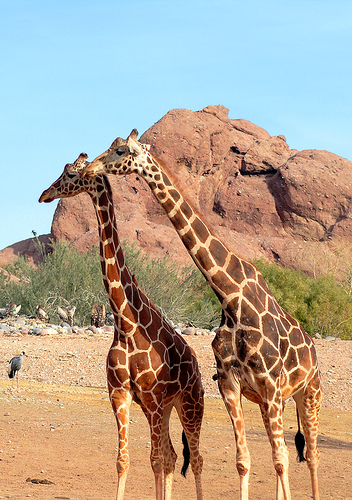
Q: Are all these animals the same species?
A: No, there are both giraffes and birds.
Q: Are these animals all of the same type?
A: No, there are both giraffes and birds.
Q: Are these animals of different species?
A: Yes, they are giraffes and birds.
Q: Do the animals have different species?
A: Yes, they are giraffes and birds.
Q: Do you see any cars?
A: No, there are no cars.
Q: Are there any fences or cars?
A: No, there are no cars or fences.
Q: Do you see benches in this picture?
A: No, there are no benches.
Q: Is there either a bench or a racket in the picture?
A: No, there are no benches or rackets.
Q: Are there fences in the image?
A: No, there are no fences.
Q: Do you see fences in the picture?
A: No, there are no fences.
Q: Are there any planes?
A: No, there are no planes.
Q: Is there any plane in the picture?
A: No, there are no airplanes.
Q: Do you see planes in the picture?
A: No, there are no planes.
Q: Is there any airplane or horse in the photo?
A: No, there are no airplanes or horses.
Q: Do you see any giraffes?
A: Yes, there is a giraffe.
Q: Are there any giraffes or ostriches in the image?
A: Yes, there is a giraffe.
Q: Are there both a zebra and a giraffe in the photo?
A: No, there is a giraffe but no zebras.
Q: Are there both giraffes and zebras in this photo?
A: No, there is a giraffe but no zebras.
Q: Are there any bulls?
A: No, there are no bulls.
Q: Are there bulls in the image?
A: No, there are no bulls.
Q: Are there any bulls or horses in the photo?
A: No, there are no bulls or horses.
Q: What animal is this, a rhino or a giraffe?
A: This is a giraffe.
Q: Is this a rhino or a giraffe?
A: This is a giraffe.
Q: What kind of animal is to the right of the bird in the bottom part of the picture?
A: The animal is a giraffe.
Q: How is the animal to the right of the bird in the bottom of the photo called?
A: The animal is a giraffe.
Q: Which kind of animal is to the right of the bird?
A: The animal is a giraffe.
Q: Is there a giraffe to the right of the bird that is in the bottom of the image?
A: Yes, there is a giraffe to the right of the bird.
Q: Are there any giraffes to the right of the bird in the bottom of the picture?
A: Yes, there is a giraffe to the right of the bird.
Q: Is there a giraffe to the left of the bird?
A: No, the giraffe is to the right of the bird.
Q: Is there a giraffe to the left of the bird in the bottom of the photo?
A: No, the giraffe is to the right of the bird.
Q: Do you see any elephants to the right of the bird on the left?
A: No, there is a giraffe to the right of the bird.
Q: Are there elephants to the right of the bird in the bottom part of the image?
A: No, there is a giraffe to the right of the bird.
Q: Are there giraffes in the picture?
A: Yes, there is a giraffe.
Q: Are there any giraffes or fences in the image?
A: Yes, there is a giraffe.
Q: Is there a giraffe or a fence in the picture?
A: Yes, there is a giraffe.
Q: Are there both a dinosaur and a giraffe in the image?
A: No, there is a giraffe but no dinosaurs.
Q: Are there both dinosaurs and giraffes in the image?
A: No, there is a giraffe but no dinosaurs.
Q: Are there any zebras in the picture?
A: No, there are no zebras.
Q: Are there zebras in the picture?
A: No, there are no zebras.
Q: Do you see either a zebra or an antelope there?
A: No, there are no zebras or antelopes.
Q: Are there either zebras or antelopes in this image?
A: No, there are no zebras or antelopes.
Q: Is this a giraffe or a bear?
A: This is a giraffe.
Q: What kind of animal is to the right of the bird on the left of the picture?
A: The animal is a giraffe.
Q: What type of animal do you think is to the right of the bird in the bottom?
A: The animal is a giraffe.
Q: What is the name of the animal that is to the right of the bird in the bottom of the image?
A: The animal is a giraffe.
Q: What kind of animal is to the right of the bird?
A: The animal is a giraffe.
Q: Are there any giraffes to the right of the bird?
A: Yes, there is a giraffe to the right of the bird.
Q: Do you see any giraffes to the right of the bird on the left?
A: Yes, there is a giraffe to the right of the bird.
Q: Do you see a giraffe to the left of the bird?
A: No, the giraffe is to the right of the bird.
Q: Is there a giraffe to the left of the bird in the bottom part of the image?
A: No, the giraffe is to the right of the bird.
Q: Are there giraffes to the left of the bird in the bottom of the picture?
A: No, the giraffe is to the right of the bird.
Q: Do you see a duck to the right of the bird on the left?
A: No, there is a giraffe to the right of the bird.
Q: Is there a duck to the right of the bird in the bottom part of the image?
A: No, there is a giraffe to the right of the bird.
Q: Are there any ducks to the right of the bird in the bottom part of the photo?
A: No, there is a giraffe to the right of the bird.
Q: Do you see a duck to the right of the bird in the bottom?
A: No, there is a giraffe to the right of the bird.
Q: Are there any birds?
A: Yes, there is a bird.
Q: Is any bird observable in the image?
A: Yes, there is a bird.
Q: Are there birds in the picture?
A: Yes, there is a bird.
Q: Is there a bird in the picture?
A: Yes, there is a bird.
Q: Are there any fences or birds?
A: Yes, there is a bird.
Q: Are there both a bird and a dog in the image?
A: No, there is a bird but no dogs.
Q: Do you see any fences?
A: No, there are no fences.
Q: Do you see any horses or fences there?
A: No, there are no fences or horses.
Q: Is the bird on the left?
A: Yes, the bird is on the left of the image.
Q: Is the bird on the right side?
A: No, the bird is on the left of the image.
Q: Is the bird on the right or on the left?
A: The bird is on the left of the image.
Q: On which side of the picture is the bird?
A: The bird is on the left of the image.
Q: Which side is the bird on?
A: The bird is on the left of the image.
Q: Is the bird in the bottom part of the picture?
A: Yes, the bird is in the bottom of the image.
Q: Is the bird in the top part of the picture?
A: No, the bird is in the bottom of the image.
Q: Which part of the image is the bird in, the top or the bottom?
A: The bird is in the bottom of the image.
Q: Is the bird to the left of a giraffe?
A: Yes, the bird is to the left of a giraffe.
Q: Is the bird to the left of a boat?
A: No, the bird is to the left of a giraffe.